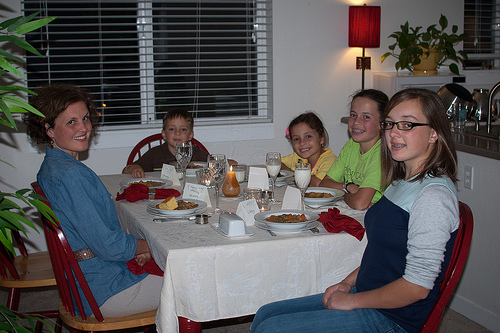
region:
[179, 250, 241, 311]
small lines in white table cloth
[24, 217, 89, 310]
red back of wooden chair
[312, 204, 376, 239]
red napkin on table top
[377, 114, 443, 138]
girl wearing black frame glasses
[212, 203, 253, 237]
white butter dish on table top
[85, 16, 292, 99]
gray blinds on the window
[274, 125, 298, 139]
pink barette in girl's hair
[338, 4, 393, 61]
red lampshade on lamp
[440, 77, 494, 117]
silver pots on top of counter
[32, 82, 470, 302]
people sitting at table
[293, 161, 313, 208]
a crystal glass of cold milk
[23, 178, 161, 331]
a red and brown chair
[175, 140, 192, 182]
a glass of water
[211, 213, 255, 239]
a white butter dish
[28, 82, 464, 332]
a family posing for a picture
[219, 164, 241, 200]
a pear shaped candle that's lite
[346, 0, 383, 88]
a red lamp thats turned on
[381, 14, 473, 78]
a green leaf plant in a yellow pot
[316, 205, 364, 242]
a red cloth napkin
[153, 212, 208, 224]
silverware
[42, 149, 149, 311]
blue denim button down shirt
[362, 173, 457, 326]
blue and grey tee shirt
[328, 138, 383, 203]
green cotton tee shirt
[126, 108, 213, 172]
boy sitting on chair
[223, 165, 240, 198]
brown lit candle on table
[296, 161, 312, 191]
milk in drinking glass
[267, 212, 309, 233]
white bowl on table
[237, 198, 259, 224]
white place card on table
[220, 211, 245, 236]
white ceramic butter plate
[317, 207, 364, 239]
red fabric napkin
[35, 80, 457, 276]
a group sitting at a dining table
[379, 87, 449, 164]
the head of a person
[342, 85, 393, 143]
the head of a person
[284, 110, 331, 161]
the head of a person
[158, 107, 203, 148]
the head of a person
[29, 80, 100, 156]
the head of a person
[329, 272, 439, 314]
the arm of a person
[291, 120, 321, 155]
the face of a girl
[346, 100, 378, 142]
the face of a girl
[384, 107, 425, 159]
the face of a girl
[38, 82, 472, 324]
a family sitting down to have dinner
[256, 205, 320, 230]
a white bowl of food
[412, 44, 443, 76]
a yellow plant pot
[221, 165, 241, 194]
a pair shapped candle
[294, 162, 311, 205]
a glass of milk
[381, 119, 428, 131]
a pair of black glasses